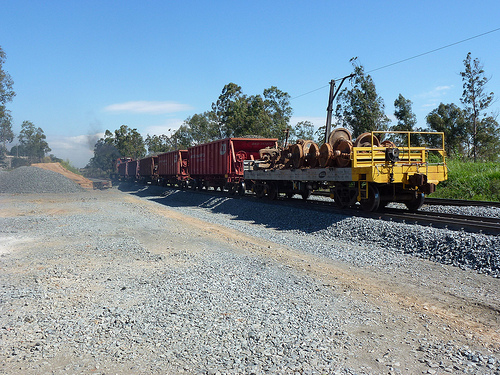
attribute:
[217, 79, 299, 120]
tops — tree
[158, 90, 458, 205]
train — driving, red, track, car, back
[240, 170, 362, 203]
track — tire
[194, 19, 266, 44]
sky — blue, clear, beautiful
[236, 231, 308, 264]
dirt — underneath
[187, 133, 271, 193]
cart — red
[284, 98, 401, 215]
truck — small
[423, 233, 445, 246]
stone — small, rock, uniform, group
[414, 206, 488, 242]
rail — way, small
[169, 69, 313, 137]
tree — beautiful, group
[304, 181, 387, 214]
wheel — black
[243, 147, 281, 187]
object — black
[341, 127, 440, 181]
railing — yellow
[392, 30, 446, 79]
line — power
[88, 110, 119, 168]
smoke — coming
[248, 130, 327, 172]
root — white